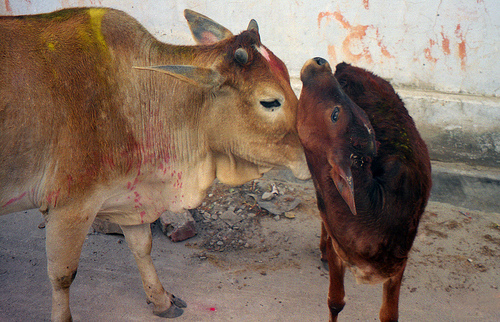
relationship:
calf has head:
[296, 56, 434, 320] [295, 54, 379, 181]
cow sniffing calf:
[0, 6, 312, 320] [296, 56, 434, 320]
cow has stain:
[0, 6, 312, 320] [258, 46, 284, 80]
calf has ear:
[296, 56, 434, 320] [328, 153, 359, 218]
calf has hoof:
[296, 56, 434, 320] [326, 299, 347, 318]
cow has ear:
[0, 6, 312, 320] [182, 7, 235, 45]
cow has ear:
[0, 6, 312, 320] [132, 63, 223, 88]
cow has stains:
[0, 6, 312, 320] [4, 107, 186, 225]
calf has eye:
[296, 56, 434, 320] [330, 104, 341, 123]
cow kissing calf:
[0, 6, 312, 320] [296, 56, 434, 320]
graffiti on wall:
[315, 0, 470, 65] [0, 1, 499, 214]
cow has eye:
[0, 6, 312, 320] [258, 100, 282, 111]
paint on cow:
[38, 6, 114, 79] [0, 6, 312, 320]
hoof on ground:
[145, 294, 189, 317] [1, 177, 500, 321]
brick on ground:
[157, 206, 198, 243] [1, 177, 500, 321]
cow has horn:
[0, 6, 312, 320] [247, 18, 259, 32]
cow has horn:
[0, 6, 312, 320] [233, 47, 252, 64]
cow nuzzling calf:
[0, 6, 312, 320] [296, 56, 434, 320]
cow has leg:
[0, 6, 312, 320] [44, 208, 97, 321]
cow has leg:
[0, 6, 312, 320] [117, 221, 186, 318]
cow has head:
[0, 6, 312, 320] [200, 29, 312, 181]